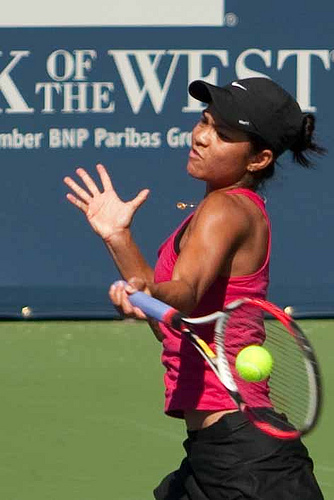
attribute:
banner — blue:
[3, 4, 330, 320]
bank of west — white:
[1, 48, 332, 121]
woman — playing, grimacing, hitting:
[66, 78, 322, 498]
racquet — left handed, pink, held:
[115, 281, 319, 436]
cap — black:
[188, 76, 307, 144]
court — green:
[8, 318, 329, 500]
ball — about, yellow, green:
[237, 344, 271, 382]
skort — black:
[150, 408, 323, 497]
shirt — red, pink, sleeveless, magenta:
[146, 189, 272, 411]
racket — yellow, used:
[182, 327, 214, 362]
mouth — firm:
[186, 144, 210, 158]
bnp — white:
[43, 128, 89, 149]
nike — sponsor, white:
[228, 77, 247, 91]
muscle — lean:
[181, 188, 235, 297]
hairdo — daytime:
[255, 87, 333, 170]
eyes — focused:
[193, 109, 237, 145]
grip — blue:
[115, 282, 175, 324]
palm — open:
[67, 160, 147, 238]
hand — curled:
[108, 277, 154, 324]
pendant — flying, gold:
[169, 199, 201, 212]